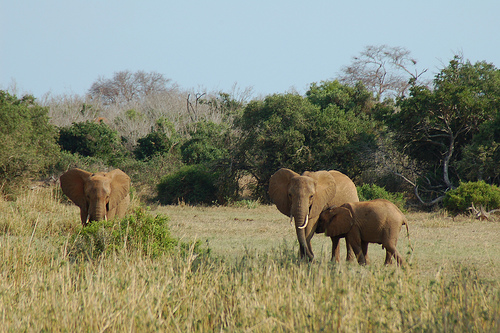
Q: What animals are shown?
A: Elephants.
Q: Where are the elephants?
A: In the wild.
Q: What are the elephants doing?
A: Eating.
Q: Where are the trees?
A: Behind the elephants.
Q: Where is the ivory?
A: In the tusks.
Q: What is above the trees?
A: The skies.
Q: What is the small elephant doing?
A: Nursing.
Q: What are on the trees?
A: Leaves.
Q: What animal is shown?
A: Elephant.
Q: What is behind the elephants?
A: Trees.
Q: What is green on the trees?
A: Leaves.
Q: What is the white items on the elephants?
A: Tusks.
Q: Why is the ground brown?
A: Dry.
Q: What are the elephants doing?
A: Standing.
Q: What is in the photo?
A: Some elephants.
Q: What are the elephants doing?
A: Walking.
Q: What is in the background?
A: Many trees.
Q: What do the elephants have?
A: Tusks.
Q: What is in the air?
A: Nothing.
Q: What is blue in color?
A: The sky.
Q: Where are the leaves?
A: On the tree.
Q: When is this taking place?
A: Daylight.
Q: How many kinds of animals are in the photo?
A: One.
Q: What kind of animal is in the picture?
A: Elephant.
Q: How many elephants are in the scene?
A: Three.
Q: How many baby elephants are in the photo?
A: One.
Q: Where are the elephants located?
A: Field.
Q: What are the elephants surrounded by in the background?
A: Trees.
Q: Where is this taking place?
A: Savannah.